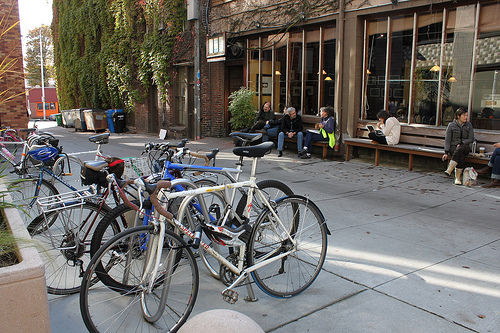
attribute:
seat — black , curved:
[228, 134, 282, 165]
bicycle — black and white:
[68, 143, 344, 325]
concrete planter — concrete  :
[0, 175, 52, 331]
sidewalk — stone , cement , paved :
[4, 122, 499, 332]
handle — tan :
[154, 174, 171, 218]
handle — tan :
[115, 178, 144, 216]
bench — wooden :
[338, 113, 499, 175]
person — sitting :
[440, 91, 484, 181]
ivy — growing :
[50, 3, 190, 108]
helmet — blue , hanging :
[19, 145, 66, 166]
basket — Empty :
[120, 155, 167, 192]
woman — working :
[366, 111, 401, 148]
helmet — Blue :
[25, 142, 65, 169]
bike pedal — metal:
[220, 287, 240, 304]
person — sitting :
[248, 95, 278, 141]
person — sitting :
[277, 107, 306, 157]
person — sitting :
[301, 106, 337, 156]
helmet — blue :
[27, 143, 59, 163]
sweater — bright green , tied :
[318, 127, 336, 150]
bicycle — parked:
[78, 140, 331, 331]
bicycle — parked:
[89, 146, 299, 295]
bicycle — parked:
[30, 137, 228, 294]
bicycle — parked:
[7, 131, 110, 235]